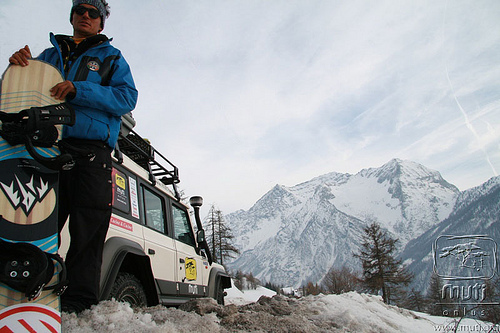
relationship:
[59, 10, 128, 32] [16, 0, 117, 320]
sunglasses on man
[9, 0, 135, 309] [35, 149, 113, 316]
man wearing pants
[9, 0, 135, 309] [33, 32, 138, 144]
man in blue coat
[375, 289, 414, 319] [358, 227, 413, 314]
snow on tree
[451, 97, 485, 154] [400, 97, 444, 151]
streaks in sky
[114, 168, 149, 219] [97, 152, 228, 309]
stickers on car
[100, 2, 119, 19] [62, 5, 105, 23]
snow hat on sunglasses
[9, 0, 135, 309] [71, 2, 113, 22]
man wearing snow hat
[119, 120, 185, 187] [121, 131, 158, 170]
rooftrack for carrying luggage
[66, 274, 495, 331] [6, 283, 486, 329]
snow on ground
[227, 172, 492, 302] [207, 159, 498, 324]
snow on top of mountain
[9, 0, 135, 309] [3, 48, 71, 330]
man holding snowboard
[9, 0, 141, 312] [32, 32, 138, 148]
man wearing blue coat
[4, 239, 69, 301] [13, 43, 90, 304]
foot strap attached to snowboard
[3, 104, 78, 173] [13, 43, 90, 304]
foot strap attached to snowboard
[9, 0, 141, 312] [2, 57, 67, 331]
man holding snowboard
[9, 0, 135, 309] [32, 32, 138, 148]
man wearing blue coat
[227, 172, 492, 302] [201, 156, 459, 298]
snow covering mountain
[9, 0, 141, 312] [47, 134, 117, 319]
man wearing pants